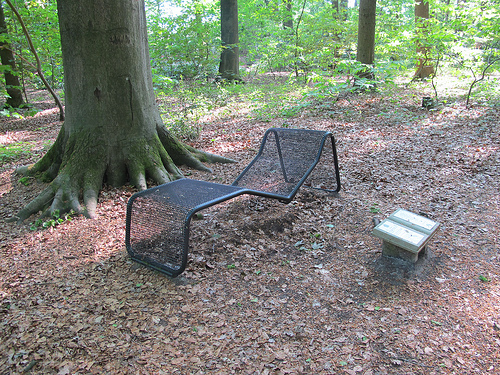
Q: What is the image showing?
A: It is showing a forest.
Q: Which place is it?
A: It is a forest.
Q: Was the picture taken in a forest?
A: Yes, it was taken in a forest.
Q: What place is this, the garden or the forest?
A: It is the forest.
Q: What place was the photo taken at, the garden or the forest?
A: It was taken at the forest.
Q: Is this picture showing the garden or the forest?
A: It is showing the forest.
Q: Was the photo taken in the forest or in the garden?
A: It was taken at the forest.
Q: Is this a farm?
A: No, it is a forest.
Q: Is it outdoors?
A: Yes, it is outdoors.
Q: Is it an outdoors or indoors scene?
A: It is outdoors.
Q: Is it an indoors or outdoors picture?
A: It is outdoors.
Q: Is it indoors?
A: No, it is outdoors.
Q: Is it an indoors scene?
A: No, it is outdoors.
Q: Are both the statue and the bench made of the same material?
A: No, the statue is made of cement and the bench is made of metal.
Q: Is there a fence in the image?
A: No, there are no fences.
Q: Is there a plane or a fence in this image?
A: No, there are no fences or airplanes.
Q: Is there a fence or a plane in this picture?
A: No, there are no fences or airplanes.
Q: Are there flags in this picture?
A: No, there are no flags.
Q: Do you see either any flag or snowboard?
A: No, there are no flags or snowboards.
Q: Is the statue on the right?
A: Yes, the statue is on the right of the image.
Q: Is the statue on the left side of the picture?
A: No, the statue is on the right of the image.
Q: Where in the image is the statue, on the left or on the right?
A: The statue is on the right of the image.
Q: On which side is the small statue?
A: The statue is on the right of the image.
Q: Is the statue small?
A: Yes, the statue is small.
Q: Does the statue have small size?
A: Yes, the statue is small.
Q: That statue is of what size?
A: The statue is small.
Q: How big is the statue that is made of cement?
A: The statue is small.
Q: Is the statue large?
A: No, the statue is small.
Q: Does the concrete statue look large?
A: No, the statue is small.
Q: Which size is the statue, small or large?
A: The statue is small.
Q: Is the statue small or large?
A: The statue is small.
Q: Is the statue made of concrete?
A: Yes, the statue is made of concrete.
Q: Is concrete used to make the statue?
A: Yes, the statue is made of concrete.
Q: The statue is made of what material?
A: The statue is made of concrete.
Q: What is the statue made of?
A: The statue is made of concrete.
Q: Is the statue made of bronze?
A: No, the statue is made of concrete.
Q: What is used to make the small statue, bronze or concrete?
A: The statue is made of concrete.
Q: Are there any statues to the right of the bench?
A: Yes, there is a statue to the right of the bench.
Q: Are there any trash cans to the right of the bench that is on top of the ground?
A: No, there is a statue to the right of the bench.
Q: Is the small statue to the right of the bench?
A: Yes, the statue is to the right of the bench.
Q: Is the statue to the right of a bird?
A: No, the statue is to the right of the bench.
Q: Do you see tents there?
A: No, there are no tents.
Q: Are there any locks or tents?
A: No, there are no tents or locks.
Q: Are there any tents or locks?
A: No, there are no tents or locks.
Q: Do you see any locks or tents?
A: No, there are no tents or locks.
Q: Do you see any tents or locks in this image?
A: No, there are no tents or locks.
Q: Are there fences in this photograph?
A: No, there are no fences.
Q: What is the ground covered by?
A: The ground is covered by the leaves.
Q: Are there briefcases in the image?
A: No, there are no briefcases.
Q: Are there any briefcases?
A: No, there are no briefcases.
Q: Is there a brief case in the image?
A: No, there are no briefcases.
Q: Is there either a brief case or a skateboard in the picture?
A: No, there are no briefcases or skateboards.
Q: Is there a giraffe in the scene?
A: No, there are no giraffes.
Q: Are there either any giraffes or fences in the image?
A: No, there are no giraffes or fences.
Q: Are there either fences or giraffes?
A: No, there are no giraffes or fences.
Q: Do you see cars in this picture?
A: No, there are no cars.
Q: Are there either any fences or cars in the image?
A: No, there are no cars or fences.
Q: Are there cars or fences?
A: No, there are no cars or fences.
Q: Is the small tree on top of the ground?
A: Yes, the tree is on top of the ground.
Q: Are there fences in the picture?
A: No, there are no fences.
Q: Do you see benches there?
A: Yes, there is a bench.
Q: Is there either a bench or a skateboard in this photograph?
A: Yes, there is a bench.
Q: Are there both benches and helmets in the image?
A: No, there is a bench but no helmets.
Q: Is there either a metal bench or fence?
A: Yes, there is a metal bench.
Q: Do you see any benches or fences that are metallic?
A: Yes, the bench is metallic.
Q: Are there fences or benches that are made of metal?
A: Yes, the bench is made of metal.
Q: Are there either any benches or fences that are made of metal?
A: Yes, the bench is made of metal.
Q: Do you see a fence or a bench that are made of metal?
A: Yes, the bench is made of metal.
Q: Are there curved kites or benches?
A: Yes, there is a curved bench.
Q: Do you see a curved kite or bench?
A: Yes, there is a curved bench.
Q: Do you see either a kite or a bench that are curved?
A: Yes, the bench is curved.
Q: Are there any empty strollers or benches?
A: Yes, there is an empty bench.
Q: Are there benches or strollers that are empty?
A: Yes, the bench is empty.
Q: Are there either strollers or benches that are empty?
A: Yes, the bench is empty.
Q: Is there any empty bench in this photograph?
A: Yes, there is an empty bench.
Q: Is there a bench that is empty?
A: Yes, there is a bench that is empty.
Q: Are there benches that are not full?
A: Yes, there is a empty bench.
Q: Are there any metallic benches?
A: Yes, there is a metal bench.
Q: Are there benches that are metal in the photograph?
A: Yes, there is a metal bench.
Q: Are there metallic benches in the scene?
A: Yes, there is a metal bench.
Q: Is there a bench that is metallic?
A: Yes, there is a bench that is metallic.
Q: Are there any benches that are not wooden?
A: Yes, there is a metallic bench.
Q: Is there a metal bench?
A: Yes, there is a bench that is made of metal.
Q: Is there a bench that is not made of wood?
A: Yes, there is a bench that is made of metal.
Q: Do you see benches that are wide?
A: Yes, there is a wide bench.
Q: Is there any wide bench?
A: Yes, there is a wide bench.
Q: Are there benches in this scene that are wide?
A: Yes, there is a bench that is wide.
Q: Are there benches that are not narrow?
A: Yes, there is a wide bench.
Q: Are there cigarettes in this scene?
A: No, there are no cigarettes.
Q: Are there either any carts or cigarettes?
A: No, there are no cigarettes or carts.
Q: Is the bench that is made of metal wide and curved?
A: Yes, the bench is wide and curved.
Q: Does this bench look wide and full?
A: No, the bench is wide but empty.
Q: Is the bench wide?
A: Yes, the bench is wide.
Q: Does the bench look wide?
A: Yes, the bench is wide.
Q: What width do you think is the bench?
A: The bench is wide.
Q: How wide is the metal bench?
A: The bench is wide.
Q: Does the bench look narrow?
A: No, the bench is wide.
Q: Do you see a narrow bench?
A: No, there is a bench but it is wide.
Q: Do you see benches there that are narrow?
A: No, there is a bench but it is wide.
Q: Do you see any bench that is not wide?
A: No, there is a bench but it is wide.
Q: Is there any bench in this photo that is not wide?
A: No, there is a bench but it is wide.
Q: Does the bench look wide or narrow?
A: The bench is wide.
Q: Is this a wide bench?
A: Yes, this is a wide bench.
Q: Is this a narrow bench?
A: No, this is a wide bench.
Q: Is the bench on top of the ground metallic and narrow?
A: No, the bench is metallic but wide.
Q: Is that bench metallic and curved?
A: Yes, the bench is metallic and curved.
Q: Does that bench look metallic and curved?
A: Yes, the bench is metallic and curved.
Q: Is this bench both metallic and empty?
A: Yes, the bench is metallic and empty.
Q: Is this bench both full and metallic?
A: No, the bench is metallic but empty.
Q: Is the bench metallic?
A: Yes, the bench is metallic.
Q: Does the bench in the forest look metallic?
A: Yes, the bench is metallic.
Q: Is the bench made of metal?
A: Yes, the bench is made of metal.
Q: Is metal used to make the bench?
A: Yes, the bench is made of metal.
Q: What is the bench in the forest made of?
A: The bench is made of metal.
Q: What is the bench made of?
A: The bench is made of metal.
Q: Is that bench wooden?
A: No, the bench is metallic.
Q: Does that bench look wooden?
A: No, the bench is metallic.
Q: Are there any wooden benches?
A: No, there is a bench but it is metallic.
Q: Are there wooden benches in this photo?
A: No, there is a bench but it is metallic.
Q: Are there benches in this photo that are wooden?
A: No, there is a bench but it is metallic.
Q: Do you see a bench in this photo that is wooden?
A: No, there is a bench but it is metallic.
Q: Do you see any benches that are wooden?
A: No, there is a bench but it is metallic.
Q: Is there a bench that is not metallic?
A: No, there is a bench but it is metallic.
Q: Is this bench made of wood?
A: No, the bench is made of metal.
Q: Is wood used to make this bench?
A: No, the bench is made of metal.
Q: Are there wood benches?
A: No, there is a bench but it is made of metal.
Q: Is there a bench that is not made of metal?
A: No, there is a bench but it is made of metal.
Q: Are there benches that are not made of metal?
A: No, there is a bench but it is made of metal.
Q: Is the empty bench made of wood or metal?
A: The bench is made of metal.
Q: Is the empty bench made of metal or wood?
A: The bench is made of metal.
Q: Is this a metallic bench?
A: Yes, this is a metallic bench.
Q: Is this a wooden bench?
A: No, this is a metallic bench.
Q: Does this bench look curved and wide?
A: Yes, the bench is curved and wide.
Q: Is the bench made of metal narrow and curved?
A: No, the bench is curved but wide.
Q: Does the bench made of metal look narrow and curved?
A: No, the bench is curved but wide.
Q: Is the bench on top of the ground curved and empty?
A: Yes, the bench is curved and empty.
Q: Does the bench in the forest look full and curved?
A: No, the bench is curved but empty.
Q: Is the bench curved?
A: Yes, the bench is curved.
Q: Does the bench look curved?
A: Yes, the bench is curved.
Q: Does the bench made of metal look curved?
A: Yes, the bench is curved.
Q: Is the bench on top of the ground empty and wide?
A: Yes, the bench is empty and wide.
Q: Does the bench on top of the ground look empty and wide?
A: Yes, the bench is empty and wide.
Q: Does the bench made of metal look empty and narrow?
A: No, the bench is empty but wide.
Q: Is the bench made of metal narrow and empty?
A: No, the bench is empty but wide.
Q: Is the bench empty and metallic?
A: Yes, the bench is empty and metallic.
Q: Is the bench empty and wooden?
A: No, the bench is empty but metallic.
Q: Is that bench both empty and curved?
A: Yes, the bench is empty and curved.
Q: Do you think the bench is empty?
A: Yes, the bench is empty.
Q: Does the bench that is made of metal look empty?
A: Yes, the bench is empty.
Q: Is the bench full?
A: No, the bench is empty.